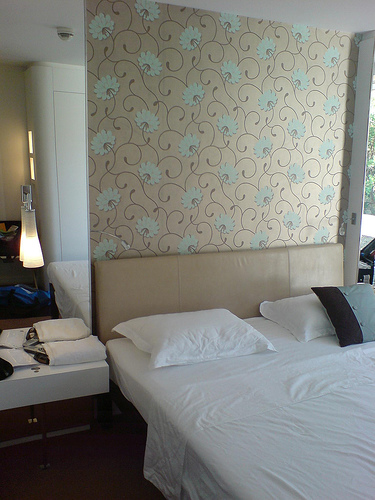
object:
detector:
[56, 27, 74, 42]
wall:
[84, 0, 363, 261]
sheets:
[104, 314, 375, 499]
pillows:
[110, 283, 375, 372]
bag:
[0, 283, 59, 320]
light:
[19, 180, 45, 270]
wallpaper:
[84, 0, 364, 264]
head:
[92, 244, 352, 343]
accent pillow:
[311, 281, 375, 346]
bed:
[105, 318, 374, 499]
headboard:
[93, 243, 344, 345]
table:
[0, 347, 110, 409]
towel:
[24, 318, 91, 347]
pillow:
[111, 308, 278, 371]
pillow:
[258, 293, 337, 344]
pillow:
[310, 283, 374, 348]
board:
[93, 242, 345, 347]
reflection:
[24, 64, 88, 263]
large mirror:
[0, 0, 92, 348]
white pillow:
[256, 293, 336, 343]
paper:
[0, 329, 27, 350]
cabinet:
[23, 61, 91, 289]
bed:
[91, 242, 375, 499]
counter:
[0, 317, 110, 413]